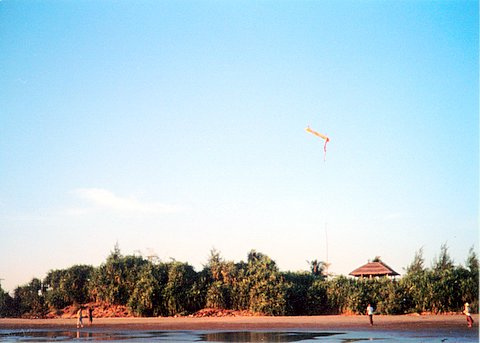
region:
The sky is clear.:
[234, 34, 465, 134]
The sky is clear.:
[209, 34, 320, 138]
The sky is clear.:
[186, 1, 434, 171]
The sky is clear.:
[219, 42, 472, 207]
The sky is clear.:
[138, 31, 308, 81]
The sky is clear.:
[147, 5, 456, 92]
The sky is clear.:
[121, 14, 345, 166]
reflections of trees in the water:
[167, 316, 342, 341]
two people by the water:
[68, 301, 97, 327]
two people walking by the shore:
[72, 303, 97, 327]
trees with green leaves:
[96, 235, 301, 313]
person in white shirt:
[358, 301, 382, 325]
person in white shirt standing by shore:
[363, 301, 380, 326]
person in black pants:
[359, 294, 383, 330]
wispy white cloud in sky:
[72, 182, 195, 242]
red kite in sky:
[300, 122, 350, 180]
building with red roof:
[350, 255, 403, 287]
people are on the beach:
[60, 297, 478, 327]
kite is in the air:
[296, 121, 335, 155]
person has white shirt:
[357, 299, 394, 331]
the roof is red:
[351, 262, 394, 275]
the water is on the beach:
[199, 320, 305, 341]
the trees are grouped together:
[15, 275, 477, 314]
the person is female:
[454, 299, 477, 329]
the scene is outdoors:
[4, 58, 475, 341]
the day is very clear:
[3, 57, 466, 341]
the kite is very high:
[294, 124, 340, 147]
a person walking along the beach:
[75, 307, 85, 329]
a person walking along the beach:
[86, 306, 94, 322]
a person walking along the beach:
[364, 302, 377, 323]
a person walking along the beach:
[462, 302, 475, 326]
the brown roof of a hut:
[349, 254, 396, 275]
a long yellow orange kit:
[306, 119, 335, 159]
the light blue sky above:
[2, 3, 477, 284]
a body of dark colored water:
[3, 321, 478, 340]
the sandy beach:
[2, 317, 477, 330]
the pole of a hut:
[360, 271, 364, 279]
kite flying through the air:
[276, 115, 358, 183]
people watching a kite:
[62, 298, 102, 336]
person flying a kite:
[303, 117, 379, 331]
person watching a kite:
[449, 290, 479, 338]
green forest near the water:
[107, 251, 298, 301]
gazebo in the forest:
[341, 256, 404, 303]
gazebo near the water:
[345, 251, 401, 303]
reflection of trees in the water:
[194, 326, 340, 340]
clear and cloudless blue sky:
[79, 112, 218, 179]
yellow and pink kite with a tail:
[287, 111, 355, 169]